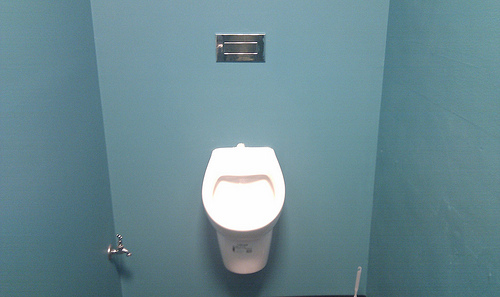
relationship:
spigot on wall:
[115, 234, 132, 259] [306, 20, 378, 110]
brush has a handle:
[350, 264, 362, 297] [354, 264, 365, 278]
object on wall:
[215, 30, 266, 66] [306, 20, 378, 110]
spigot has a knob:
[115, 234, 132, 259] [118, 235, 122, 242]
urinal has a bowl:
[192, 134, 291, 278] [217, 183, 269, 212]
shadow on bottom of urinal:
[225, 277, 270, 293] [192, 134, 291, 278]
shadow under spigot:
[225, 277, 270, 293] [115, 234, 132, 259]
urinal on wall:
[192, 134, 291, 278] [306, 20, 378, 110]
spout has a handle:
[121, 244, 133, 257] [354, 264, 365, 278]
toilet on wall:
[215, 160, 275, 238] [306, 20, 378, 110]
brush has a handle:
[350, 290, 362, 297] [354, 264, 365, 278]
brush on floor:
[350, 290, 362, 297] [311, 295, 498, 296]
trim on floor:
[376, 31, 390, 51] [311, 295, 498, 296]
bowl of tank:
[217, 183, 269, 212] [222, 145, 267, 157]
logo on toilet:
[221, 246, 261, 260] [215, 160, 275, 238]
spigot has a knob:
[106, 234, 132, 262] [118, 235, 122, 242]